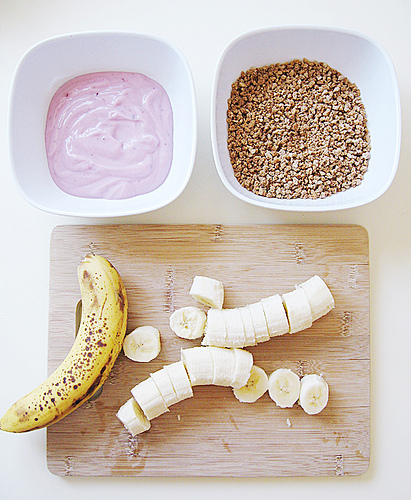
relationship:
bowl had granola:
[211, 25, 402, 213] [227, 58, 371, 199]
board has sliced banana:
[48, 221, 372, 478] [230, 365, 267, 403]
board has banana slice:
[48, 221, 372, 478] [268, 367, 328, 415]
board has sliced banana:
[48, 221, 372, 478] [233, 346, 252, 386]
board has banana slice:
[48, 221, 372, 478] [169, 306, 205, 341]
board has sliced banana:
[48, 221, 372, 478] [299, 373, 330, 413]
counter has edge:
[13, 182, 385, 498] [313, 468, 409, 498]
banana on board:
[291, 273, 337, 327] [45, 223, 371, 478]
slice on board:
[297, 273, 340, 317] [48, 221, 372, 478]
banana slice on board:
[301, 374, 329, 415] [48, 221, 372, 478]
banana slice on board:
[268, 367, 328, 415] [48, 221, 372, 478]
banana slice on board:
[120, 324, 163, 362] [48, 221, 372, 478]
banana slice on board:
[167, 304, 205, 339] [48, 221, 372, 478]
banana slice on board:
[187, 272, 226, 307] [48, 221, 372, 478]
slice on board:
[114, 396, 149, 435] [45, 223, 371, 478]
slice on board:
[204, 344, 236, 390] [48, 221, 372, 478]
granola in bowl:
[227, 58, 371, 199] [204, 25, 398, 213]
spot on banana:
[81, 314, 105, 366] [0, 203, 152, 449]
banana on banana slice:
[0, 252, 128, 434] [268, 367, 328, 415]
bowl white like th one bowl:
[8, 30, 197, 214] [204, 25, 398, 213]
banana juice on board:
[92, 399, 147, 476] [45, 223, 371, 478]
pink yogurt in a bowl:
[44, 71, 171, 197] [8, 31, 197, 219]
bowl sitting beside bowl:
[204, 25, 398, 213] [4, 24, 195, 223]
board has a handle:
[45, 223, 371, 478] [73, 297, 84, 332]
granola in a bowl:
[225, 58, 375, 199] [204, 25, 398, 213]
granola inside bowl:
[225, 58, 375, 199] [204, 25, 398, 213]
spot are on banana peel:
[81, 314, 105, 366] [86, 270, 104, 355]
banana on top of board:
[0, 253, 125, 439] [45, 223, 371, 478]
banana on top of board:
[115, 275, 335, 438] [45, 223, 371, 478]